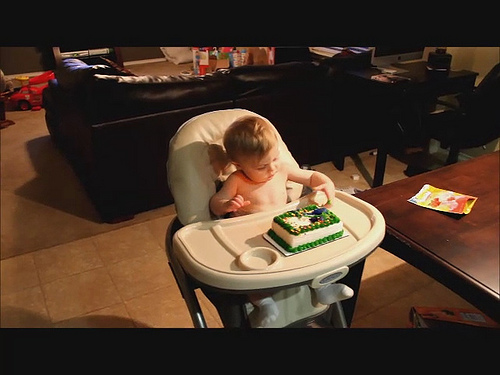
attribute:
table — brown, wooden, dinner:
[339, 145, 496, 335]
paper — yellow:
[418, 180, 478, 228]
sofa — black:
[40, 61, 352, 220]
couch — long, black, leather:
[2, 42, 484, 254]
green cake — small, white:
[263, 203, 338, 236]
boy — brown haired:
[173, 108, 323, 230]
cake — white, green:
[259, 201, 348, 258]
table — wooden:
[372, 125, 499, 332]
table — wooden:
[348, 145, 498, 297]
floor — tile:
[61, 258, 135, 308]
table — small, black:
[321, 62, 498, 154]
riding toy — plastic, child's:
[8, 73, 60, 115]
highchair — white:
[159, 107, 388, 330]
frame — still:
[160, 218, 351, 327]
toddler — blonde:
[211, 116, 356, 329]